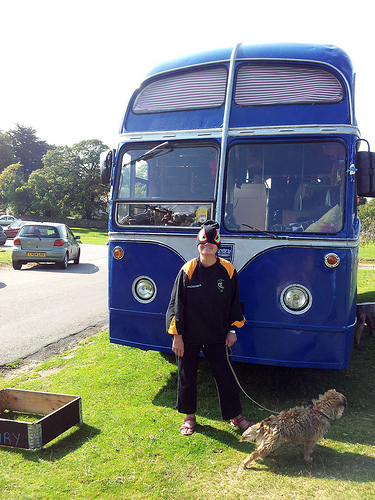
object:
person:
[165, 220, 253, 435]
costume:
[165, 219, 245, 421]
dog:
[241, 388, 348, 471]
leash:
[224, 348, 277, 414]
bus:
[106, 43, 374, 372]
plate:
[27, 251, 46, 258]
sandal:
[179, 414, 197, 436]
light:
[281, 284, 313, 315]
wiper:
[123, 141, 169, 167]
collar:
[312, 405, 330, 419]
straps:
[180, 423, 194, 431]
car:
[11, 220, 81, 270]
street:
[0, 233, 110, 365]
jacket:
[165, 255, 246, 338]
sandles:
[230, 414, 254, 432]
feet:
[179, 415, 198, 435]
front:
[107, 42, 346, 368]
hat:
[197, 220, 222, 250]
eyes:
[214, 229, 221, 243]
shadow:
[23, 262, 98, 275]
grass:
[1, 228, 374, 499]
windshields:
[222, 140, 349, 236]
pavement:
[0, 242, 111, 368]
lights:
[131, 276, 157, 305]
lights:
[112, 245, 125, 260]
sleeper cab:
[110, 129, 353, 237]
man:
[354, 299, 372, 345]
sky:
[0, 0, 375, 153]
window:
[118, 144, 218, 232]